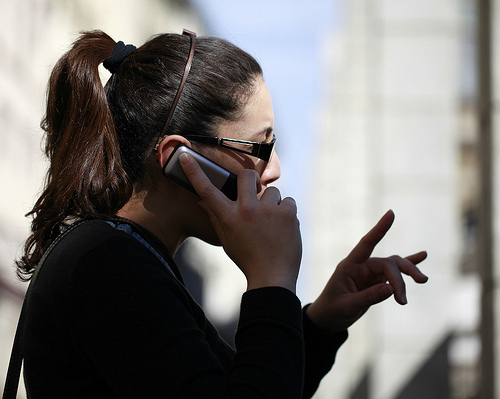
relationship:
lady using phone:
[17, 28, 428, 398] [163, 144, 238, 198]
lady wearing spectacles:
[17, 28, 428, 398] [156, 133, 275, 161]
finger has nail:
[345, 283, 395, 313] [401, 292, 408, 300]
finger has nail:
[178, 154, 230, 217] [180, 154, 189, 163]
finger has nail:
[356, 284, 392, 306] [380, 285, 388, 296]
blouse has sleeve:
[23, 218, 347, 399] [101, 288, 303, 398]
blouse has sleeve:
[23, 218, 347, 399] [302, 303, 347, 399]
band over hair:
[161, 30, 195, 152] [14, 28, 262, 281]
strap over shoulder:
[3, 216, 177, 399] [43, 227, 168, 313]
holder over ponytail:
[104, 41, 136, 71] [15, 24, 116, 282]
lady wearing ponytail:
[17, 28, 428, 398] [15, 24, 116, 282]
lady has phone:
[17, 28, 428, 398] [163, 144, 238, 198]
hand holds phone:
[182, 153, 302, 287] [163, 144, 238, 198]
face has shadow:
[245, 125, 281, 188] [218, 144, 255, 169]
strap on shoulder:
[3, 216, 177, 399] [43, 227, 168, 313]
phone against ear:
[163, 144, 238, 198] [157, 135, 191, 167]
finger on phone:
[178, 154, 230, 217] [163, 144, 238, 198]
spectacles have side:
[156, 133, 275, 161] [160, 135, 259, 155]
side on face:
[160, 135, 259, 155] [245, 125, 281, 188]